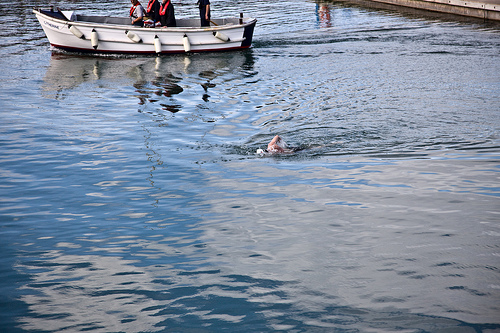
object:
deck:
[38, 9, 238, 29]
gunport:
[212, 30, 231, 42]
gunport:
[182, 33, 189, 52]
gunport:
[153, 34, 162, 57]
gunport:
[125, 29, 144, 43]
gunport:
[90, 28, 98, 50]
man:
[256, 134, 345, 157]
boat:
[29, 7, 259, 54]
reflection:
[311, 0, 336, 30]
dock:
[347, 0, 500, 24]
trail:
[250, 18, 498, 51]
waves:
[0, 197, 500, 333]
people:
[129, 0, 211, 29]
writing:
[44, 20, 60, 29]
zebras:
[0, 92, 177, 333]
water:
[1, 0, 500, 333]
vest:
[143, 0, 171, 16]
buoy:
[67, 24, 87, 40]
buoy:
[90, 28, 98, 50]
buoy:
[125, 28, 144, 44]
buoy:
[152, 35, 162, 58]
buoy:
[181, 33, 191, 53]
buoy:
[212, 30, 231, 44]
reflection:
[5, 0, 500, 333]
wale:
[42, 44, 209, 57]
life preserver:
[159, 0, 171, 15]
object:
[254, 134, 346, 158]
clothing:
[141, 8, 177, 27]